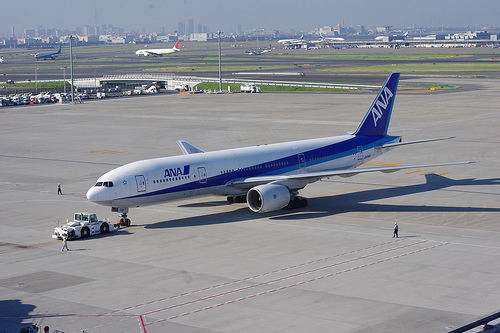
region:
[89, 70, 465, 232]
A blue and white plane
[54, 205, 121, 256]
White taxi vehicle pulling plane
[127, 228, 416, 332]
Red lines on the ground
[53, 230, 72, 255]
man standing by taxi vehicle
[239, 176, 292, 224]
jet engine of plane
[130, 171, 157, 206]
Front door of plane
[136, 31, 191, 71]
A white plane with red wing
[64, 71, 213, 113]
A bridge on the runway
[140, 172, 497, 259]
Shadow of plane on the ground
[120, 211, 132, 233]
Front tires of plane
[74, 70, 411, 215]
ANA Aircraft on tarmac.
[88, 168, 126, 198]
Cockpit of ABA aircraft.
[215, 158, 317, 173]
Many side windows in aircraft.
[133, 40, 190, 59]
Plane enroute to destination.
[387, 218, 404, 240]
Person walking on airport tarmac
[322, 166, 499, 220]
Shadow of ANA aircraft.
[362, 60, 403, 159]
ANA tail of airplane.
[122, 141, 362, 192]
Fuselage of the ANA airplane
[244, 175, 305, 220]
Engine hanging from the wing of airplane.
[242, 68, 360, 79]
Runway at airport.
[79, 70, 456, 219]
ANA Airplane on the tarmac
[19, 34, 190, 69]
Multiple airplanes rolling down the runway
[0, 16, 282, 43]
Skyline in the distance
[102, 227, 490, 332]
Three red striped lines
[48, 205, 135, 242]
White airport utility vehicle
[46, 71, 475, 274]
Men walking around an airplane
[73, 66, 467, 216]
White airplane with light and dark blue stripes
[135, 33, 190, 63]
White plane with a red tail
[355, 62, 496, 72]
Strip of green grass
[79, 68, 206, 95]
Bridge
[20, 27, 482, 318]
This is an airport scene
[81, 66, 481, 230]
A jumbo jet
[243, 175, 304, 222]
This is one of the jet's engines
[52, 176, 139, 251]
A vehicle is towing the jet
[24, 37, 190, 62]
Other planes are in the background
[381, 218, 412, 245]
A person is standing here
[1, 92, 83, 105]
Ground vehicles are parked here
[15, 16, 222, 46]
A city is shown in the distance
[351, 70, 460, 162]
The plane's tail section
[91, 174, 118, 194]
These are the cockpit windows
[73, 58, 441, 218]
Large blue and white plane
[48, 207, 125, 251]
Taxi vehicle pulling plane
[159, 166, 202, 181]
ANA in blue on the plane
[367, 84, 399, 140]
ANA in white on the plane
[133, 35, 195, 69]
White plane with red wing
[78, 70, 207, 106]
Small bridge on runway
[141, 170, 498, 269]
Shadown on ground from plane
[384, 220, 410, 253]
Man standing on ground to the right of the plane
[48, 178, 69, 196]
Man standing on ground to left of plane